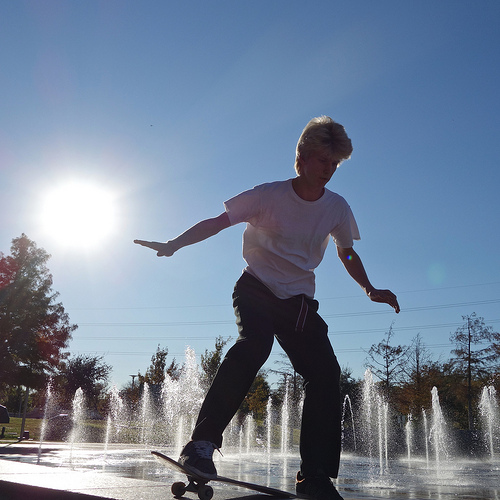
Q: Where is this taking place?
A: Outdoors on a fountain.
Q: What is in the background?
A: Water fountain.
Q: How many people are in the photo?
A: One.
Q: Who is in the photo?
A: A boy.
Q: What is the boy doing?
A: Skateboarding.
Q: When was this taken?
A: During the day.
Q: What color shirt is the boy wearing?
A: White.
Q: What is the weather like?
A: Sunny.